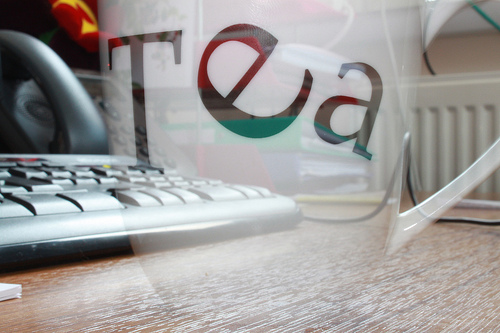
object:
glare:
[95, 10, 494, 313]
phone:
[4, 25, 144, 166]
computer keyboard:
[0, 153, 300, 264]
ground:
[366, 87, 398, 135]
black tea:
[97, 0, 424, 300]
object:
[51, 0, 112, 42]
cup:
[93, 0, 498, 321]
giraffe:
[0, 18, 111, 159]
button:
[56, 192, 123, 211]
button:
[9, 193, 81, 215]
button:
[1, 195, 32, 218]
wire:
[299, 130, 498, 224]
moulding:
[203, 1, 490, 83]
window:
[203, 2, 410, 29]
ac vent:
[402, 69, 500, 223]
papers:
[1, 284, 22, 303]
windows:
[28, 138, 293, 273]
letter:
[105, 28, 183, 175]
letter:
[197, 21, 312, 138]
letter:
[312, 59, 373, 157]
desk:
[0, 187, 499, 331]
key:
[99, 175, 120, 188]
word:
[106, 20, 384, 177]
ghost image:
[93, 0, 483, 316]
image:
[0, 3, 499, 333]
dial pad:
[103, 163, 113, 169]